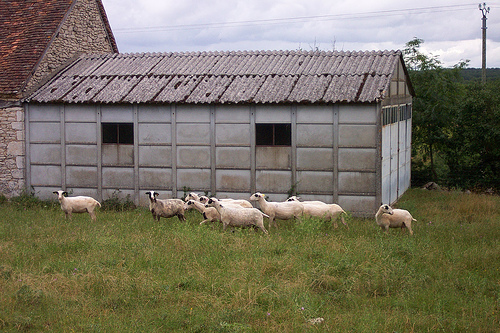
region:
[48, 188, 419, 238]
goats in a field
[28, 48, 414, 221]
building connected to house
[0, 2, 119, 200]
stone bilding on far left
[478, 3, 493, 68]
utility pole in field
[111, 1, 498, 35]
utilty lines in the air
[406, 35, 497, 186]
trees along a fence row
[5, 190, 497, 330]
the green field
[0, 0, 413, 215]
the grey shed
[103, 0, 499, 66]
the cloudy sky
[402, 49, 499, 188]
the green bushes on the side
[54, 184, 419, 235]
the white sheep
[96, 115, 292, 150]
the openings on the shed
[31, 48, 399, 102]
the grey picketed roof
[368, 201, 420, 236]
the last sheep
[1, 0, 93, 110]
the brown roof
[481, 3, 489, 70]
the street pole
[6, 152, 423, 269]
animals on the grass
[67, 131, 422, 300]
white animals on ground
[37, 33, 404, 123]
roof of the building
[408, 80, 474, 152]
tree next to building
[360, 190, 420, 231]
one white animal on ground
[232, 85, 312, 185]
window on the building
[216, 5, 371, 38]
clouds above the land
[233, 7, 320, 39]
wires above the land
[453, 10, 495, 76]
pole in the distance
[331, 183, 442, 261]
animal with head turned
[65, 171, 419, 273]
herd of white goats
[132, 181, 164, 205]
black and white face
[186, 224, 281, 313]
green and long grass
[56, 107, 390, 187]
grey building behind goats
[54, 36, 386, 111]
building has grey roof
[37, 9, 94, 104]
stone wall on building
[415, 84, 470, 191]
green bushes behind goats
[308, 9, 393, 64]
grey and white sky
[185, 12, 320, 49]
puffy clouds in sky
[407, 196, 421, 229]
goat has white tail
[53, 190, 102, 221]
Goat to the left of the others.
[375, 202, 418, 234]
Goat to the right of the others.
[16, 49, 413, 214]
Grey building with dark roof.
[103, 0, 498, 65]
A blue cloudy sky.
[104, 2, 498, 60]
White clouds in a blue sky.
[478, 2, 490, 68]
A tall light pole.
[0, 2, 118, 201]
A stone building with red roof.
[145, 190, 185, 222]
Darkest goat looking at the camera.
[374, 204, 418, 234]
White goat looking behind its self.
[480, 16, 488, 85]
A tall brown pole.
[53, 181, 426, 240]
sheep in the green grass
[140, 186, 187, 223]
sheep in the green grass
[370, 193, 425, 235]
sheep in the green grass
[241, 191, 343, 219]
sheep in the green grass